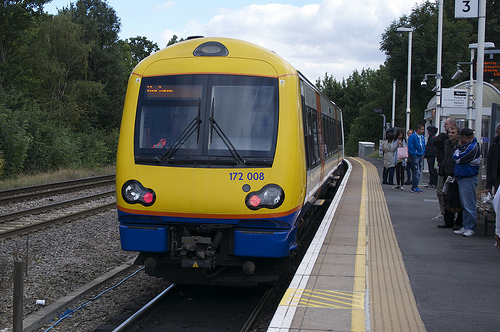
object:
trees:
[0, 0, 180, 178]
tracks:
[1, 190, 116, 239]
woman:
[392, 128, 412, 191]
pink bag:
[395, 145, 410, 160]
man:
[406, 119, 426, 195]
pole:
[406, 32, 414, 130]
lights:
[394, 24, 417, 34]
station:
[264, 78, 499, 331]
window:
[142, 82, 199, 100]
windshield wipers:
[210, 96, 245, 168]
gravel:
[66, 256, 78, 270]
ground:
[0, 156, 500, 331]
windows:
[206, 85, 278, 156]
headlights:
[241, 190, 263, 211]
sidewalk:
[264, 156, 500, 332]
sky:
[30, 0, 436, 87]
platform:
[269, 155, 500, 332]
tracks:
[108, 282, 274, 331]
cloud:
[120, 0, 423, 88]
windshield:
[209, 85, 278, 160]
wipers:
[152, 95, 202, 168]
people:
[451, 126, 483, 238]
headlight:
[260, 180, 287, 209]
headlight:
[119, 176, 141, 204]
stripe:
[345, 155, 368, 331]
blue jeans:
[408, 153, 423, 188]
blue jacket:
[405, 129, 428, 157]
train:
[114, 34, 344, 289]